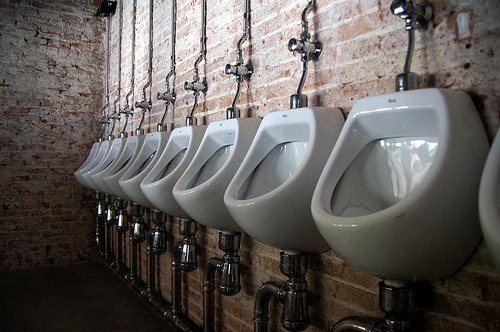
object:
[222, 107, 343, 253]
urinal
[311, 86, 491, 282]
urinal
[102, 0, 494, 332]
brick wall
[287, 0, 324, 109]
metal pipe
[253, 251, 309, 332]
pipe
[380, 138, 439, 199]
reflection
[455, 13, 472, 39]
white spot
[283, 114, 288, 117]
words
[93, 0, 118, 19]
object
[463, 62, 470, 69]
black spot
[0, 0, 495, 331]
men's room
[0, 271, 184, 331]
floor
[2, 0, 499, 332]
photo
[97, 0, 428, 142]
light